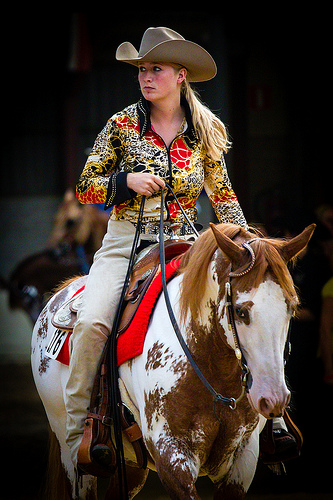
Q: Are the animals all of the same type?
A: Yes, all the animals are horses.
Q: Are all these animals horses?
A: Yes, all the animals are horses.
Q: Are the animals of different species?
A: No, all the animals are horses.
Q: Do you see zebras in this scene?
A: No, there are no zebras.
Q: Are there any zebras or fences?
A: No, there are no zebras or fences.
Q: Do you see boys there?
A: No, there are no boys.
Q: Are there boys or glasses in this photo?
A: No, there are no boys or glasses.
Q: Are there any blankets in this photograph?
A: Yes, there is a blanket.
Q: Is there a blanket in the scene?
A: Yes, there is a blanket.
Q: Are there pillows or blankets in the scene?
A: Yes, there is a blanket.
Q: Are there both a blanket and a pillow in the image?
A: No, there is a blanket but no pillows.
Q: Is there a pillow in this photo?
A: No, there are no pillows.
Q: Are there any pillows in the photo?
A: No, there are no pillows.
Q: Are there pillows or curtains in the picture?
A: No, there are no pillows or curtains.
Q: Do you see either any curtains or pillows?
A: No, there are no pillows or curtains.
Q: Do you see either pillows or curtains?
A: No, there are no pillows or curtains.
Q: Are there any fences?
A: No, there are no fences.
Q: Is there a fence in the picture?
A: No, there are no fences.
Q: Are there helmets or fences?
A: No, there are no fences or helmets.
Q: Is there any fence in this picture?
A: No, there are no fences.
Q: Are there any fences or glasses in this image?
A: No, there are no fences or glasses.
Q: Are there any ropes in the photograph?
A: No, there are no ropes.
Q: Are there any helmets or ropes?
A: No, there are no ropes or helmets.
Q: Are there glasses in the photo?
A: No, there are no glasses.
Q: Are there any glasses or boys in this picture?
A: No, there are no glasses or boys.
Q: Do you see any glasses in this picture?
A: No, there are no glasses.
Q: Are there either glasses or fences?
A: No, there are no glasses or fences.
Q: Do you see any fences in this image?
A: No, there are no fences.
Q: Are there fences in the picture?
A: No, there are no fences.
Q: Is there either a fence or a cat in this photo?
A: No, there are no fences or cats.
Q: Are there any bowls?
A: No, there are no bowls.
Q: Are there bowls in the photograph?
A: No, there are no bowls.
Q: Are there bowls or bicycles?
A: No, there are no bowls or bicycles.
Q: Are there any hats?
A: Yes, there is a hat.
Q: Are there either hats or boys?
A: Yes, there is a hat.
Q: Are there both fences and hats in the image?
A: No, there is a hat but no fences.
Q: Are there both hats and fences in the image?
A: No, there is a hat but no fences.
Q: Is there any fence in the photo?
A: No, there are no fences.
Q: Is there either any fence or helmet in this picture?
A: No, there are no fences or helmets.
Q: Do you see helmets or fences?
A: No, there are no fences or helmets.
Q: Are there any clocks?
A: No, there are no clocks.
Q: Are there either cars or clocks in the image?
A: No, there are no clocks or cars.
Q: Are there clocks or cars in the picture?
A: No, there are no clocks or cars.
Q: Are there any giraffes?
A: No, there are no giraffes.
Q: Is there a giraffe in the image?
A: No, there are no giraffes.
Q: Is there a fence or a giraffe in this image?
A: No, there are no giraffes or fences.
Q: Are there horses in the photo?
A: Yes, there is a horse.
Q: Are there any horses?
A: Yes, there is a horse.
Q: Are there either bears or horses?
A: Yes, there is a horse.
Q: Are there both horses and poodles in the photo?
A: No, there is a horse but no poodles.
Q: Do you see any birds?
A: No, there are no birds.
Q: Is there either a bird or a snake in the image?
A: No, there are no birds or snakes.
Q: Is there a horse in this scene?
A: Yes, there is a horse.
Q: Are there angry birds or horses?
A: Yes, there is a horse.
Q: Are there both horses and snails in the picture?
A: No, there is a horse but no snails.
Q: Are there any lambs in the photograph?
A: No, there are no lambs.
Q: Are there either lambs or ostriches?
A: No, there are no lambs or ostriches.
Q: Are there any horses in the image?
A: Yes, there is a horse.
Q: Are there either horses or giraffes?
A: Yes, there is a horse.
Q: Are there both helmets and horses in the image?
A: No, there is a horse but no helmets.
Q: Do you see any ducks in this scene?
A: No, there are no ducks.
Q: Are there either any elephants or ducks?
A: No, there are no ducks or elephants.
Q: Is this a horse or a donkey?
A: This is a horse.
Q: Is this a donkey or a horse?
A: This is a horse.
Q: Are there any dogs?
A: No, there are no dogs.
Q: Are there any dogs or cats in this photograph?
A: No, there are no dogs or cats.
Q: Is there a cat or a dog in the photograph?
A: No, there are no dogs or cats.